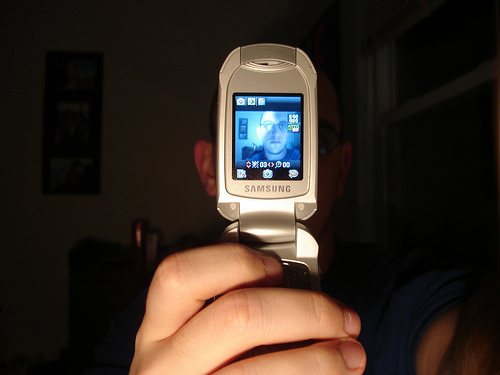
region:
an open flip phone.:
[200, 36, 330, 297]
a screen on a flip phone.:
[224, 85, 312, 197]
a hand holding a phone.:
[133, 233, 386, 372]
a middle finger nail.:
[333, 298, 382, 345]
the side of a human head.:
[170, 111, 219, 233]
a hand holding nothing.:
[403, 299, 465, 364]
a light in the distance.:
[100, 197, 159, 306]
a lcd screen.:
[217, 81, 314, 213]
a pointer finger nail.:
[255, 241, 297, 283]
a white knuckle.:
[111, 289, 183, 374]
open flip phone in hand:
[195, 32, 336, 281]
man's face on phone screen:
[255, 103, 301, 162]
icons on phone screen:
[230, 163, 297, 184]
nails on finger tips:
[255, 251, 368, 367]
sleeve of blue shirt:
[378, 274, 453, 363]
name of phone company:
[238, 179, 297, 200]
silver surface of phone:
[224, 46, 309, 88]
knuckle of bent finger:
[147, 244, 199, 297]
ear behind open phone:
[187, 135, 222, 200]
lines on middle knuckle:
[226, 285, 273, 335]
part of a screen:
[248, 116, 305, 184]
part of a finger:
[251, 280, 297, 335]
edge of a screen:
[288, 131, 325, 234]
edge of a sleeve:
[395, 307, 435, 345]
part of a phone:
[223, 164, 272, 229]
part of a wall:
[118, 115, 163, 180]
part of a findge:
[248, 278, 285, 327]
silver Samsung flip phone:
[216, 41, 319, 309]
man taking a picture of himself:
[95, 41, 492, 366]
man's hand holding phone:
[135, 41, 365, 371]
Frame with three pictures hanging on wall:
[40, 47, 101, 202]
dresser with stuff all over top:
[66, 214, 200, 369]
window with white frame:
[338, 38, 495, 262]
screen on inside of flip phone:
[230, 91, 303, 184]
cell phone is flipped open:
[213, 41, 323, 371]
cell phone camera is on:
[217, 43, 322, 328]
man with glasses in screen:
[256, 111, 289, 156]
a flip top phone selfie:
[214, 37, 324, 288]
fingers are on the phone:
[126, 242, 369, 372]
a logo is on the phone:
[241, 181, 295, 196]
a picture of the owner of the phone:
[240, 107, 302, 172]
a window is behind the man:
[358, 6, 498, 296]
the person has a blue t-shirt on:
[70, 243, 487, 373]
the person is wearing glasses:
[203, 120, 339, 159]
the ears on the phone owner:
[188, 133, 355, 214]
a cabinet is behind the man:
[63, 240, 172, 365]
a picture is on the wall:
[36, 87, 105, 208]